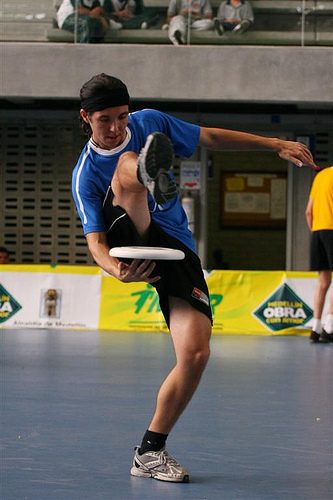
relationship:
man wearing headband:
[67, 73, 252, 419] [56, 63, 144, 109]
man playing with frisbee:
[71, 72, 318, 443] [105, 241, 188, 266]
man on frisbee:
[71, 72, 318, 443] [109, 245, 185, 259]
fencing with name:
[1, 264, 332, 333] [263, 300, 305, 325]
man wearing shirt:
[71, 72, 318, 443] [57, 124, 173, 226]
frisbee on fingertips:
[105, 244, 188, 261] [113, 259, 163, 281]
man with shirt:
[71, 72, 318, 443] [55, 132, 250, 241]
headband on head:
[80, 84, 129, 113] [78, 71, 129, 148]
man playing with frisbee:
[71, 72, 318, 443] [105, 241, 186, 262]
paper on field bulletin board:
[254, 191, 269, 214] [219, 170, 288, 229]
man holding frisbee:
[71, 72, 318, 443] [99, 240, 187, 269]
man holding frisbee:
[71, 72, 318, 443] [107, 246, 184, 259]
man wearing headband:
[71, 72, 318, 443] [80, 91, 131, 113]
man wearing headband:
[71, 72, 318, 443] [76, 92, 134, 111]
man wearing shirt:
[71, 72, 318, 443] [71, 109, 200, 246]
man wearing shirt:
[71, 72, 318, 443] [65, 103, 200, 242]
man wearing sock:
[298, 149, 331, 351] [306, 312, 323, 336]